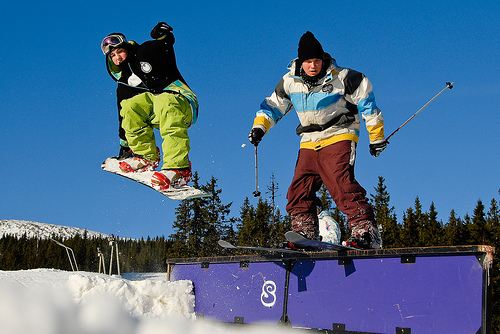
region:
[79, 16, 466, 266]
the people doing snow sports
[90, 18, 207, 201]
the person snow boarding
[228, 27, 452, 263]
the person skiing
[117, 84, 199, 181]
the light green pants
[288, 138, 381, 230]
the brown pants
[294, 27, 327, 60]
the black beanie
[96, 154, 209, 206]
the snow board in mid air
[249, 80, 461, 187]
the ski poles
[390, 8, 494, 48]
the clear blue sky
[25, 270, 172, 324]
the mound of white snow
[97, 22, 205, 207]
a snowboarder in air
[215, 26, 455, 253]
a skier on a platform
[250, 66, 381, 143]
a white blue yellow and black winter coat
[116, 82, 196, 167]
a lime green pair of snow pants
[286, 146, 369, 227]
a maroon pair of snow pants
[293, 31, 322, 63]
a black stocking cap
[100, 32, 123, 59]
a pair of protective eyewear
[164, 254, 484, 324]
a purple platform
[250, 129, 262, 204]
a silver ski pole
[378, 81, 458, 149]
a silver ski pole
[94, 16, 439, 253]
Two people jumping over a purple ramp.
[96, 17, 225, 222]
A young person on a snowboard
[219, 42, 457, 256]
Young person on skis.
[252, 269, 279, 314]
A white 'S' spray painted on purple background.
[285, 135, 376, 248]
Brown snowpants worn by skier.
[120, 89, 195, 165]
Lime green snow pants worn by snowboarder.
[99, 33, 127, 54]
Snow goggles worn by snowboarder.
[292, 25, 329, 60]
Black hat worn by skier.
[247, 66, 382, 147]
White coat with yellow, blue, and grey stripes.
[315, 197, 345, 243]
Person with white coat standing behind skier and snowboarder.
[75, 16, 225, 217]
person on snowboard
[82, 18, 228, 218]
airborne person riding snowboard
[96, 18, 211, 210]
person wearing lime green pants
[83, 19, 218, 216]
person wearing protective safety goggles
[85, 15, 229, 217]
person wearing red snowboots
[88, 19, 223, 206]
person wearing warm black hooded coat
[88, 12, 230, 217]
person jumping with snowboard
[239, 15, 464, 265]
man wearing black beanie hat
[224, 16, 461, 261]
man wearing crimson pants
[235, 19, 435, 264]
man wearing multi-colored striped coat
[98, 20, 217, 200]
woman in bright green pants on snowboard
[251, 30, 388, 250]
man wearing dark red pants on skis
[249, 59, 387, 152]
black, white, blue and yellow jacket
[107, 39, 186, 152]
black jacket with white patch on chest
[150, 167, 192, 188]
red and grey ski boot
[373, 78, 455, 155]
ski pole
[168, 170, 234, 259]
three conifer trees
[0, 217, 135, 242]
snow covered hill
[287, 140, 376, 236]
dark red pants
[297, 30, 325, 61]
black beanie hat